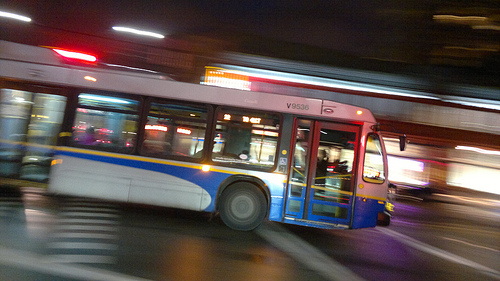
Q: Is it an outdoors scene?
A: Yes, it is outdoors.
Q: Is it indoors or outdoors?
A: It is outdoors.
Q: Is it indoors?
A: No, it is outdoors.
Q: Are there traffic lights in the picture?
A: No, there are no traffic lights.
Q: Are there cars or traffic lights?
A: No, there are no traffic lights or cars.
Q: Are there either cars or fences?
A: No, there are no cars or fences.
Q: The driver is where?
A: The driver is in the bus.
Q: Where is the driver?
A: The driver is in the bus.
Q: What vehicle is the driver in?
A: The driver is in the bus.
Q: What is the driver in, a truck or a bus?
A: The driver is in a bus.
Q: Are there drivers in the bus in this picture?
A: Yes, there is a driver in the bus.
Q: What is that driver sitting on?
A: The driver is sitting on the bus.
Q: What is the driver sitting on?
A: The driver is sitting on the bus.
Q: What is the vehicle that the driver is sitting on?
A: The vehicle is a bus.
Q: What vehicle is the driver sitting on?
A: The driver is sitting on the bus.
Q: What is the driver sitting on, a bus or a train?
A: The driver is sitting on a bus.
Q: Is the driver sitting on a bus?
A: Yes, the driver is sitting on a bus.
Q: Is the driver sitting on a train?
A: No, the driver is sitting on a bus.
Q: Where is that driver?
A: The driver is on the bus.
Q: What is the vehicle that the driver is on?
A: The vehicle is a bus.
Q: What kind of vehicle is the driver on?
A: The driver is on the bus.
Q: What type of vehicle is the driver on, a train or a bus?
A: The driver is on a bus.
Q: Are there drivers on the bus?
A: Yes, there is a driver on the bus.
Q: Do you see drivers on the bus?
A: Yes, there is a driver on the bus.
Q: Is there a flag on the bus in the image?
A: No, there is a driver on the bus.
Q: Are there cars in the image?
A: No, there are no cars.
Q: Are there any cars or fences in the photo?
A: No, there are no cars or fences.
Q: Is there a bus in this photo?
A: Yes, there is a bus.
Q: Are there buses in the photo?
A: Yes, there is a bus.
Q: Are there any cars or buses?
A: Yes, there is a bus.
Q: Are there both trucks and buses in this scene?
A: No, there is a bus but no trucks.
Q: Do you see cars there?
A: No, there are no cars.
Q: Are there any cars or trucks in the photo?
A: No, there are no cars or trucks.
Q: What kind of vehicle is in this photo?
A: The vehicle is a bus.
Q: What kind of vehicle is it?
A: The vehicle is a bus.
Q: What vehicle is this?
A: This is a bus.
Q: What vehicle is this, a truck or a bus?
A: This is a bus.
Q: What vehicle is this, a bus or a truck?
A: This is a bus.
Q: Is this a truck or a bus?
A: This is a bus.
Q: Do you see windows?
A: Yes, there is a window.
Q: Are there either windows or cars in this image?
A: Yes, there is a window.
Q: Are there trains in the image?
A: No, there are no trains.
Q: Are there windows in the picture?
A: Yes, there is a window.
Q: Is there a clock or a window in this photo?
A: Yes, there is a window.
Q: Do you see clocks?
A: No, there are no clocks.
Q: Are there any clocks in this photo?
A: No, there are no clocks.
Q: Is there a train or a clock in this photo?
A: No, there are no clocks or trains.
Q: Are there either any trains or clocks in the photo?
A: No, there are no clocks or trains.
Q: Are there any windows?
A: Yes, there is a window.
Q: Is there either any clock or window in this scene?
A: Yes, there is a window.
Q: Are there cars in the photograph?
A: No, there are no cars.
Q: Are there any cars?
A: No, there are no cars.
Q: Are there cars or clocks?
A: No, there are no cars or clocks.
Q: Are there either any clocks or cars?
A: No, there are no cars or clocks.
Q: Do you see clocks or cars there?
A: No, there are no cars or clocks.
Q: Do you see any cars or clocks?
A: No, there are no cars or clocks.